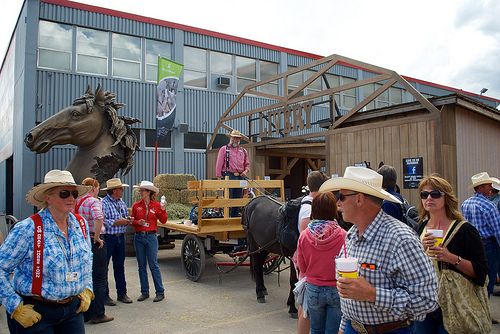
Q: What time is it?
A: Daytime.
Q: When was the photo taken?
A: Daytime.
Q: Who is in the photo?
A: A group of people.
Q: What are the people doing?
A: Walking.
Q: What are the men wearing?
A: Cowboy hats.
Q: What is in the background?
A: A building.